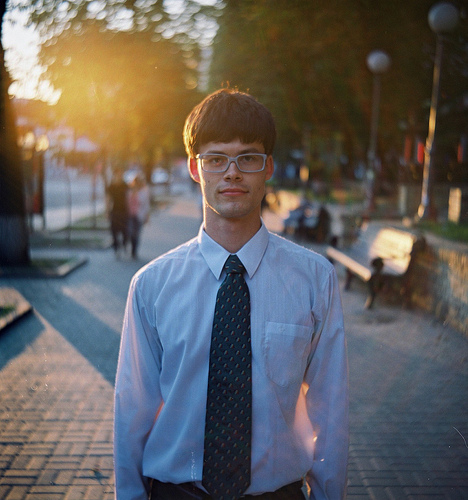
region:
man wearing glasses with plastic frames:
[192, 151, 266, 173]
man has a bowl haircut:
[182, 86, 276, 156]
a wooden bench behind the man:
[325, 224, 421, 306]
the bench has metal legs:
[363, 256, 385, 308]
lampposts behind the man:
[410, 5, 466, 229]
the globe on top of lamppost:
[428, 2, 458, 32]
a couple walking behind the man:
[106, 167, 152, 262]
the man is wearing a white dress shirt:
[108, 219, 347, 495]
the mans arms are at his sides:
[112, 258, 353, 496]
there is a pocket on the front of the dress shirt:
[263, 319, 314, 387]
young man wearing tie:
[78, 83, 381, 494]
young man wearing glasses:
[173, 91, 283, 220]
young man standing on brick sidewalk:
[39, 102, 456, 487]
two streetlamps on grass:
[341, 5, 456, 231]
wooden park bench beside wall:
[325, 205, 439, 316]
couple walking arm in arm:
[87, 162, 150, 266]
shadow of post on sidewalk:
[10, 260, 197, 487]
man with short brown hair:
[163, 73, 297, 233]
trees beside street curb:
[34, 16, 191, 227]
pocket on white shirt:
[261, 297, 328, 400]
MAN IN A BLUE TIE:
[106, 53, 360, 492]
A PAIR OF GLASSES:
[193, 146, 275, 179]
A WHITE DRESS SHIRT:
[100, 218, 362, 498]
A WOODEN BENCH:
[321, 220, 423, 316]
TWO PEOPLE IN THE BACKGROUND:
[88, 163, 170, 263]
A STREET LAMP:
[354, 37, 396, 227]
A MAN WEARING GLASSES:
[102, 83, 373, 492]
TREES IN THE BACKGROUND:
[23, 13, 194, 223]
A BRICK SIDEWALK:
[6, 350, 106, 498]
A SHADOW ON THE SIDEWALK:
[3, 266, 135, 397]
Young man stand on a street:
[93, 78, 363, 496]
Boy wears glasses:
[92, 76, 364, 498]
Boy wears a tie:
[86, 74, 376, 496]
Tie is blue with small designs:
[190, 247, 270, 496]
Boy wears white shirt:
[85, 67, 372, 496]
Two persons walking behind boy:
[93, 158, 149, 275]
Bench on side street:
[317, 210, 429, 311]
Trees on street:
[44, 4, 191, 234]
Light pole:
[401, 1, 464, 232]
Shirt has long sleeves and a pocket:
[74, 223, 368, 498]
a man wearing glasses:
[170, 93, 303, 234]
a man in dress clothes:
[144, 141, 346, 465]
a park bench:
[310, 203, 438, 316]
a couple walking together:
[88, 159, 165, 272]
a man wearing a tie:
[156, 137, 317, 497]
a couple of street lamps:
[347, 8, 463, 260]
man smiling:
[160, 92, 296, 233]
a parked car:
[273, 199, 349, 246]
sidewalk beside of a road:
[3, 358, 88, 481]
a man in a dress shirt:
[113, 223, 354, 488]